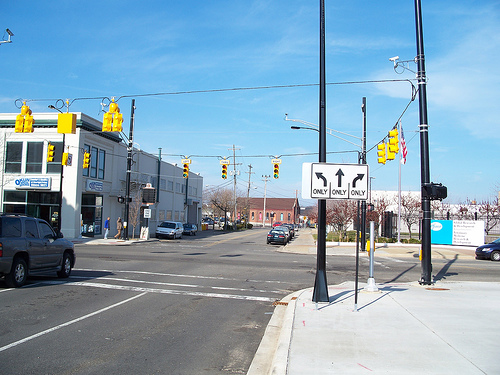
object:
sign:
[310, 163, 368, 200]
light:
[184, 164, 189, 169]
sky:
[138, 17, 273, 77]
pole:
[311, 54, 330, 303]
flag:
[398, 118, 407, 164]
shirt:
[104, 219, 111, 228]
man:
[104, 217, 111, 240]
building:
[0, 112, 203, 240]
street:
[118, 213, 308, 248]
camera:
[389, 56, 400, 66]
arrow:
[352, 174, 364, 188]